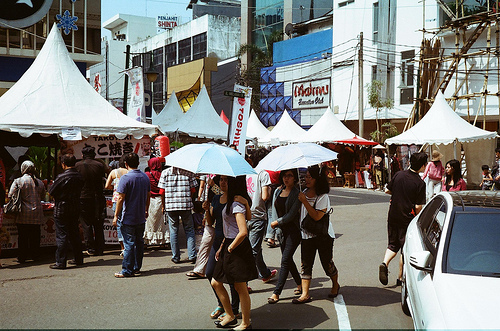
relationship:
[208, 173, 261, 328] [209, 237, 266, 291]
girl wearing skirt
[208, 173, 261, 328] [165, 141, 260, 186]
girl with umbrella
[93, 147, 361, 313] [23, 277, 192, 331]
people at street